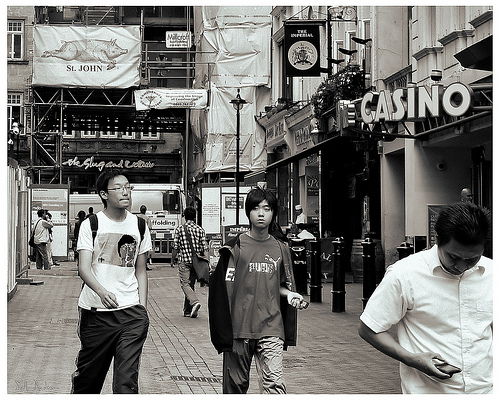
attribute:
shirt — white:
[76, 210, 150, 313]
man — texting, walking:
[356, 201, 497, 396]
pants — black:
[70, 302, 150, 394]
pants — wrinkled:
[220, 334, 288, 393]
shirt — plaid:
[172, 220, 208, 266]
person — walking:
[168, 208, 210, 318]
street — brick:
[10, 252, 400, 395]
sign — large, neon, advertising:
[331, 79, 474, 133]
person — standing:
[29, 208, 56, 271]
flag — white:
[30, 18, 144, 92]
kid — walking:
[206, 185, 307, 391]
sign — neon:
[60, 156, 156, 171]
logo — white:
[248, 254, 282, 275]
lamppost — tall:
[233, 109, 244, 228]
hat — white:
[293, 203, 302, 212]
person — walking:
[71, 166, 153, 395]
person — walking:
[208, 188, 310, 395]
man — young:
[206, 186, 309, 395]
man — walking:
[71, 164, 154, 394]